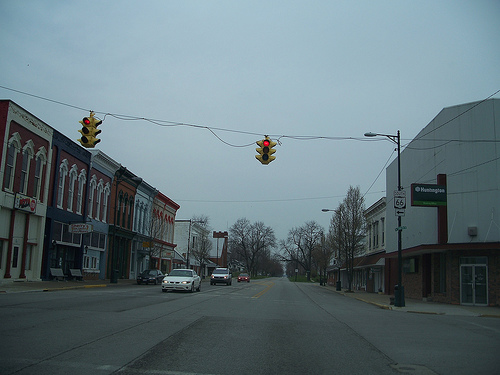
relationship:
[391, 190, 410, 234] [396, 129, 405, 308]
signs on post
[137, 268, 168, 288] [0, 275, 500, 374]
car on road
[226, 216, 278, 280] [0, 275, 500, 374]
tree behind road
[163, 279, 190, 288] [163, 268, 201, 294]
headlight on car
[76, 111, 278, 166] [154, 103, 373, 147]
lights hanging from wire